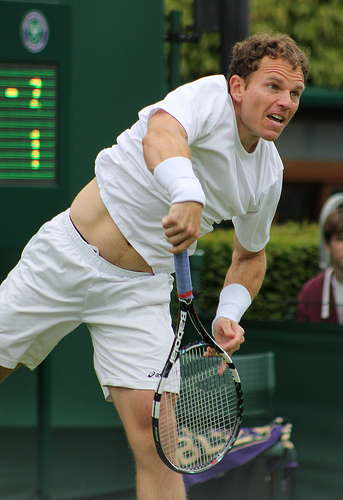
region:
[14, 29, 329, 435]
close-up of tennis player in action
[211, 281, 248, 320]
player's white wrist band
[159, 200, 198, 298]
hand and handle of a racquet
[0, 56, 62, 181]
LCD scoreboard at the court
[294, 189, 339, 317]
spectator at courtside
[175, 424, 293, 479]
purple towel on a chair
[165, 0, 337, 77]
row of hedges behind the player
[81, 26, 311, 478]
man follows through with his shot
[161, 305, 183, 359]
name of the racquet's manufacturer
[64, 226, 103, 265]
elastic band and string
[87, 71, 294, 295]
THE MAN IS WEARING A SHORT SLEEVED SHIRT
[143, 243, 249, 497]
THE MAN IS HOLDING A RACKET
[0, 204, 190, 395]
THE MAN'S SHORTS ARE WHITE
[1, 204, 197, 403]
THE MAN IS WEARING SHORT PANTS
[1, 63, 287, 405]
ALL OF THE MAN'S CLOTHING IS WHITE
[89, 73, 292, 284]
THE MAN IS WEARING A WHITE SHIRT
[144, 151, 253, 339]
THE MAN'S ARM BANDS ARE WHITE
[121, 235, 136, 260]
THE MAN'S BELLY BUTTON IS VISIBLE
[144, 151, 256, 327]
THE MAN IS WEARING ARM BANDS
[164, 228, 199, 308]
blue handle on tennis racket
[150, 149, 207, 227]
white sweatbands around man's wrist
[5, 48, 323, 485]
man playing tennis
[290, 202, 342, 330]
person watching the tennis match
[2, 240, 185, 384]
white tennis shorts with black Asics logo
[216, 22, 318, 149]
wrinkles on man's forhead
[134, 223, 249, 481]
black and blue tennis racket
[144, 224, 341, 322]
row of green hedges in the background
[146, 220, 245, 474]
the racket is held down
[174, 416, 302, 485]
a banner on the ground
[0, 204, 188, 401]
the shorts are white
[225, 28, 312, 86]
his hair is curly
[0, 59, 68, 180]
a scoreboard behind the player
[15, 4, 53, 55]
a logo over the scoreboard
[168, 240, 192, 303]
the handle is blue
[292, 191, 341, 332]
a person watching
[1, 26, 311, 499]
man playing tennis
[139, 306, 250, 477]
white and black tennis racket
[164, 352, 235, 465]
white strings on the tennis racket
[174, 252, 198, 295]
purple handle of the tennis racket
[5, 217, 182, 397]
white shorts of the tennis player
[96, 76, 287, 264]
white shirt of the tennis palyer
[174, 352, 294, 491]
green chair next to tennis court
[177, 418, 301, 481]
purple towel with gold lettering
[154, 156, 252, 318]
white wristbands of the tennis player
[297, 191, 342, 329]
man watching the tennis match